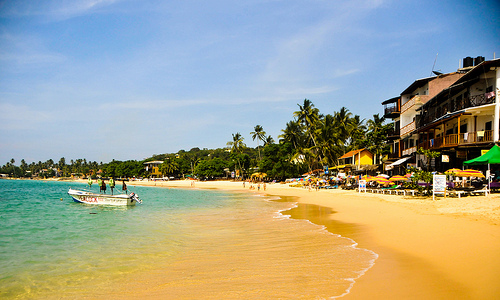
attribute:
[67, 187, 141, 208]
boat — white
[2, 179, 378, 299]
water — lovely 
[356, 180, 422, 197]
fence — small, white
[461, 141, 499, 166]
canopy — bright green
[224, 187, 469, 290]
beach — clean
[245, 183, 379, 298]
wave — gentle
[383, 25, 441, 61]
cupboard — bright blue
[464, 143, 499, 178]
umbrella —  green 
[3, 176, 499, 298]
sand — bright orange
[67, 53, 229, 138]
clouds — white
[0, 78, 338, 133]
clouds — few 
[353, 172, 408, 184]
umbrellas — yellow, orange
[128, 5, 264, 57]
sky —  white 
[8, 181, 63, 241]
ocean — blue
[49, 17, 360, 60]
sky —  blue